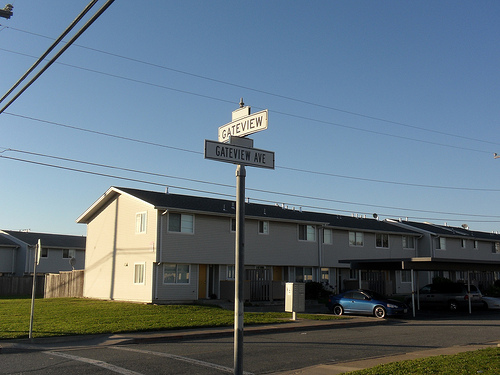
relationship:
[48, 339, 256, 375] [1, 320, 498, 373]
stripes on road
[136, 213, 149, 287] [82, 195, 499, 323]
window on house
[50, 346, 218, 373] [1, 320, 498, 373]
lines on road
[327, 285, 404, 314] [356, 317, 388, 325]
car near curb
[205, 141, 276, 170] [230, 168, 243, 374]
sign on pole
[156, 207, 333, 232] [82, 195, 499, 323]
gutter on house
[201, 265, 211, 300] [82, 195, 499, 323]
door on house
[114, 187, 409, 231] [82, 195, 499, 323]
roof on house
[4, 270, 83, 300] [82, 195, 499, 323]
fence near house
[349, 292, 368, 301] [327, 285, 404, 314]
window on car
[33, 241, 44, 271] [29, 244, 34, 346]
sign on pole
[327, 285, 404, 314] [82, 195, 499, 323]
car near house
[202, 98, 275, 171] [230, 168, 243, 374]
signs on pole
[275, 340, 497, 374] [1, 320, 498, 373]
sidewalk near road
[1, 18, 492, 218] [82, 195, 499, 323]
wires above house